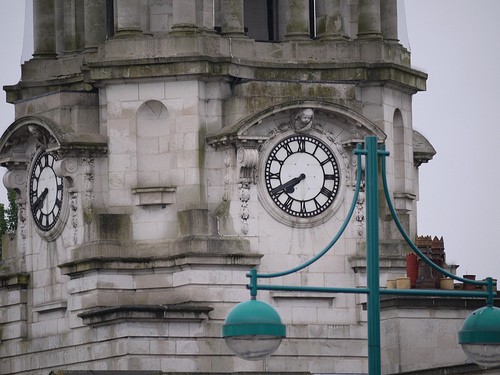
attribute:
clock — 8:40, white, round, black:
[265, 135, 339, 218]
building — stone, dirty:
[1, 0, 498, 374]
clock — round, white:
[29, 151, 64, 230]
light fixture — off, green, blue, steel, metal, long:
[221, 134, 499, 374]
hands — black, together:
[271, 173, 304, 196]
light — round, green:
[224, 298, 285, 363]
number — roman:
[296, 139, 306, 153]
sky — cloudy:
[406, 3, 496, 280]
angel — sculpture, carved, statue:
[292, 107, 314, 136]